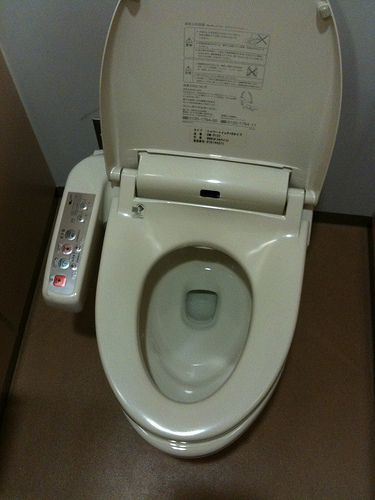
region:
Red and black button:
[47, 272, 71, 285]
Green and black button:
[58, 253, 71, 276]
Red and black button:
[59, 242, 72, 253]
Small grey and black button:
[61, 223, 88, 244]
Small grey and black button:
[73, 212, 84, 222]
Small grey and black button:
[81, 201, 91, 210]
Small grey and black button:
[74, 240, 83, 255]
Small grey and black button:
[69, 259, 81, 278]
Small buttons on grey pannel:
[48, 178, 104, 337]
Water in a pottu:
[157, 255, 238, 390]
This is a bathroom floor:
[65, 465, 93, 485]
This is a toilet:
[150, 412, 231, 474]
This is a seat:
[177, 426, 200, 445]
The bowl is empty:
[190, 382, 214, 405]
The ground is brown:
[26, 418, 124, 483]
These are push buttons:
[54, 183, 116, 254]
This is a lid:
[156, 121, 271, 176]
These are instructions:
[175, 105, 240, 148]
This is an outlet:
[74, 113, 112, 161]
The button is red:
[19, 259, 78, 298]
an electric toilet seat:
[34, 145, 335, 464]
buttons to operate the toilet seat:
[39, 180, 92, 298]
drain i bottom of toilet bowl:
[172, 284, 233, 329]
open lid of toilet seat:
[86, 14, 351, 224]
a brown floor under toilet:
[32, 158, 368, 490]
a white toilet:
[49, 150, 349, 469]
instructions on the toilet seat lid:
[167, 10, 302, 165]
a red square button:
[44, 272, 72, 295]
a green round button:
[57, 255, 75, 271]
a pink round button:
[60, 238, 79, 258]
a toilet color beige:
[30, 1, 356, 471]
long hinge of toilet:
[122, 150, 306, 215]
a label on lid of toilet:
[152, 8, 290, 164]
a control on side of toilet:
[28, 133, 318, 474]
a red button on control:
[47, 268, 71, 293]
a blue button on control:
[55, 252, 67, 271]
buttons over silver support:
[39, 176, 92, 296]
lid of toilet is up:
[81, 6, 351, 202]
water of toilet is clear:
[154, 265, 240, 380]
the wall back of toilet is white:
[8, 10, 373, 258]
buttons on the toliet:
[50, 190, 83, 292]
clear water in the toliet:
[163, 273, 219, 389]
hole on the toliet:
[197, 183, 222, 203]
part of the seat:
[171, 412, 209, 430]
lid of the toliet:
[117, 11, 303, 156]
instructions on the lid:
[174, 15, 273, 155]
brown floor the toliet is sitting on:
[24, 434, 93, 466]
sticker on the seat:
[134, 201, 148, 221]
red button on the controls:
[50, 273, 74, 290]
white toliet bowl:
[151, 346, 232, 391]